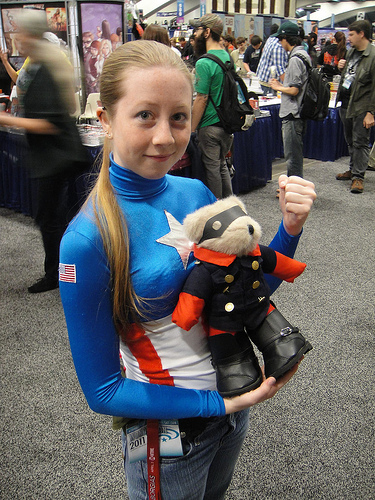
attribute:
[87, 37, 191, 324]
hair — blonde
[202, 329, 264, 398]
boot — black 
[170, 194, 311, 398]
bear — stuffed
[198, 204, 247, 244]
mask — black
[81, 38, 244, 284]
girl — young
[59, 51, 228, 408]
girl — young 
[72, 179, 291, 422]
shirt — captain america 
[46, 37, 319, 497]
girl — young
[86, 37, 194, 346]
hair — light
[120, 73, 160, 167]
complexion — fair